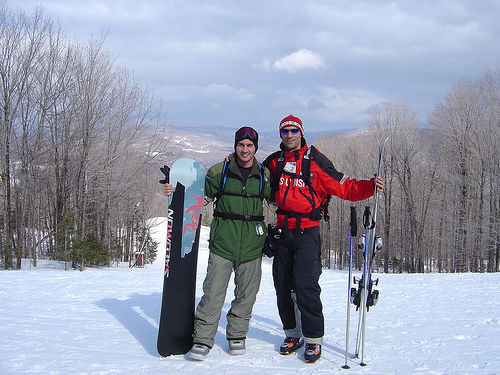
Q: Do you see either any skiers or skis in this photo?
A: Yes, there are skis.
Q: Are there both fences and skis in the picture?
A: No, there are skis but no fences.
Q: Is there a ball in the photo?
A: No, there are no balls.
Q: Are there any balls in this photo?
A: No, there are no balls.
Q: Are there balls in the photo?
A: No, there are no balls.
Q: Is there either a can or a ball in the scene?
A: No, there are no balls or cans.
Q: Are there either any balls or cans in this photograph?
A: No, there are no balls or cans.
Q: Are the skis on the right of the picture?
A: Yes, the skis are on the right of the image.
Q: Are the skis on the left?
A: No, the skis are on the right of the image.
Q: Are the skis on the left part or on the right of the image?
A: The skis are on the right of the image.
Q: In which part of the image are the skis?
A: The skis are on the right of the image.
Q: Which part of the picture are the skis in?
A: The skis are on the right of the image.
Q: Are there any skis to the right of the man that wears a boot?
A: Yes, there are skis to the right of the man.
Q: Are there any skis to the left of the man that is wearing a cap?
A: No, the skis are to the right of the man.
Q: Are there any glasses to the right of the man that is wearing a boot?
A: No, there are skis to the right of the man.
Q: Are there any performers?
A: No, there are no performers.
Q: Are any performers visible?
A: No, there are no performers.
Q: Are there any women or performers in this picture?
A: No, there are no performers or women.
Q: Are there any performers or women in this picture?
A: No, there are no performers or women.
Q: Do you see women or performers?
A: No, there are no performers or women.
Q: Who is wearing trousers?
A: The man is wearing trousers.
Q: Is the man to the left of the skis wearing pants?
A: Yes, the man is wearing pants.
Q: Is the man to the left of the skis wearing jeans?
A: No, the man is wearing pants.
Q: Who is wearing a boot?
A: The man is wearing a boot.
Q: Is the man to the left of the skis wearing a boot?
A: Yes, the man is wearing a boot.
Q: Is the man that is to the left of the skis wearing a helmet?
A: No, the man is wearing a boot.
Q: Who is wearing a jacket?
A: The man is wearing a jacket.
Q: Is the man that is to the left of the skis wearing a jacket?
A: Yes, the man is wearing a jacket.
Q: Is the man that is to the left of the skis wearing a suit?
A: No, the man is wearing a jacket.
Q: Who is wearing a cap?
A: The man is wearing a cap.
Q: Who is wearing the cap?
A: The man is wearing a cap.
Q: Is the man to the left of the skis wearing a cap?
A: Yes, the man is wearing a cap.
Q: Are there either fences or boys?
A: No, there are no fences or boys.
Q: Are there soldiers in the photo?
A: No, there are no soldiers.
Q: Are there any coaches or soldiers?
A: No, there are no soldiers or coaches.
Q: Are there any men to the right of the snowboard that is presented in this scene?
A: Yes, there is a man to the right of the snowboard.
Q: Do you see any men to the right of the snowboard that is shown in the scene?
A: Yes, there is a man to the right of the snowboard.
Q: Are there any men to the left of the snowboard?
A: No, the man is to the right of the snowboard.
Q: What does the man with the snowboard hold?
A: The man holds the skis.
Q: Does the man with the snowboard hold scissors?
A: No, the man holds the skis.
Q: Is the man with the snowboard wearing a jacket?
A: Yes, the man is wearing a jacket.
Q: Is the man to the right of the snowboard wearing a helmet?
A: No, the man is wearing a jacket.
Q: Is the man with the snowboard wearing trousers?
A: Yes, the man is wearing trousers.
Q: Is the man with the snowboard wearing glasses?
A: No, the man is wearing trousers.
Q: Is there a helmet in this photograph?
A: No, there are no helmets.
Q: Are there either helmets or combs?
A: No, there are no helmets or combs.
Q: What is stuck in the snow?
A: The pole is stuck in the snow.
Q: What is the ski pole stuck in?
A: The pole is stuck in the snow.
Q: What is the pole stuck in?
A: The pole is stuck in the snow.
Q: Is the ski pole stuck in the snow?
A: Yes, the pole is stuck in the snow.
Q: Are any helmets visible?
A: No, there are no helmets.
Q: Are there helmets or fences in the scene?
A: No, there are no helmets or fences.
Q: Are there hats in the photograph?
A: Yes, there is a hat.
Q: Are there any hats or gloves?
A: Yes, there is a hat.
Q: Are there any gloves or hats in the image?
A: Yes, there is a hat.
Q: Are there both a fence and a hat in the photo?
A: No, there is a hat but no fences.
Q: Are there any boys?
A: No, there are no boys.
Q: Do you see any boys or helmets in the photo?
A: No, there are no boys or helmets.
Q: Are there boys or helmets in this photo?
A: No, there are no boys or helmets.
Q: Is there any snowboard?
A: Yes, there is a snowboard.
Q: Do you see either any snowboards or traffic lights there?
A: Yes, there is a snowboard.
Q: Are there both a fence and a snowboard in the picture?
A: No, there is a snowboard but no fences.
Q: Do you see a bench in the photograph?
A: No, there are no benches.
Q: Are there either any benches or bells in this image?
A: No, there are no benches or bells.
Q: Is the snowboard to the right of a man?
A: No, the snowboard is to the left of a man.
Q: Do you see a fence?
A: No, there are no fences.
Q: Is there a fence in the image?
A: No, there are no fences.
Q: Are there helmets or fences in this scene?
A: No, there are no fences or helmets.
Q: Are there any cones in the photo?
A: No, there are no cones.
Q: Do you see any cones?
A: No, there are no cones.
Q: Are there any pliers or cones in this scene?
A: No, there are no cones or pliers.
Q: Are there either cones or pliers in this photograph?
A: No, there are no cones or pliers.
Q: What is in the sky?
A: The clouds are in the sky.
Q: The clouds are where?
A: The clouds are in the sky.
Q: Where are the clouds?
A: The clouds are in the sky.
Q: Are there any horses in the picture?
A: No, there are no horses.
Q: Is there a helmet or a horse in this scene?
A: No, there are no horses or helmets.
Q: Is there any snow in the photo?
A: Yes, there is snow.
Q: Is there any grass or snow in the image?
A: Yes, there is snow.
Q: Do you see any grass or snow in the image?
A: Yes, there is snow.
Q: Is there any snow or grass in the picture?
A: Yes, there is snow.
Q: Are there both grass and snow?
A: No, there is snow but no grass.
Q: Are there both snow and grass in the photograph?
A: No, there is snow but no grass.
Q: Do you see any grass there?
A: No, there is no grass.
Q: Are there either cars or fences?
A: No, there are no cars or fences.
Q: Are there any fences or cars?
A: No, there are no cars or fences.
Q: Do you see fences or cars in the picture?
A: No, there are no cars or fences.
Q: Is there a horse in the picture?
A: No, there are no horses.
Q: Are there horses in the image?
A: No, there are no horses.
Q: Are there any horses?
A: No, there are no horses.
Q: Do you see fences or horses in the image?
A: No, there are no horses or fences.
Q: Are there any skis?
A: Yes, there are skis.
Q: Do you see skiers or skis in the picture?
A: Yes, there are skis.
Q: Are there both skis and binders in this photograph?
A: No, there are skis but no binders.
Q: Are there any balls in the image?
A: No, there are no balls.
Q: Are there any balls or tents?
A: No, there are no balls or tents.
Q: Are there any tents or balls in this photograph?
A: No, there are no balls or tents.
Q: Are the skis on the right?
A: Yes, the skis are on the right of the image.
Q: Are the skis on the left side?
A: No, the skis are on the right of the image.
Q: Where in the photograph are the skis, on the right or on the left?
A: The skis are on the right of the image.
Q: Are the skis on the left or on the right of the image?
A: The skis are on the right of the image.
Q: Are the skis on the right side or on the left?
A: The skis are on the right of the image.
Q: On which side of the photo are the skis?
A: The skis are on the right of the image.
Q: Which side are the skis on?
A: The skis are on the right of the image.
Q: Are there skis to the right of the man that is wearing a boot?
A: Yes, there are skis to the right of the man.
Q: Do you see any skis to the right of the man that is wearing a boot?
A: Yes, there are skis to the right of the man.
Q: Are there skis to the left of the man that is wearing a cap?
A: No, the skis are to the right of the man.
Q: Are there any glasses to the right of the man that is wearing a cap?
A: No, there are skis to the right of the man.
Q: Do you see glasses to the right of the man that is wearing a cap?
A: No, there are skis to the right of the man.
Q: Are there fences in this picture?
A: No, there are no fences.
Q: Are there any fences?
A: No, there are no fences.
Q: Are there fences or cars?
A: No, there are no fences or cars.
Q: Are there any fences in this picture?
A: No, there are no fences.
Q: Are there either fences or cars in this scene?
A: No, there are no fences or cars.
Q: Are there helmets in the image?
A: No, there are no helmets.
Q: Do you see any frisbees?
A: No, there are no frisbees.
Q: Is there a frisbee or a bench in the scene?
A: No, there are no frisbees or benches.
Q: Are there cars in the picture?
A: No, there are no cars.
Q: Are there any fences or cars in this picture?
A: No, there are no cars or fences.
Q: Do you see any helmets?
A: No, there are no helmets.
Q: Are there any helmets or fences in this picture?
A: No, there are no helmets or fences.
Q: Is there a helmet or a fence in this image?
A: No, there are no helmets or fences.